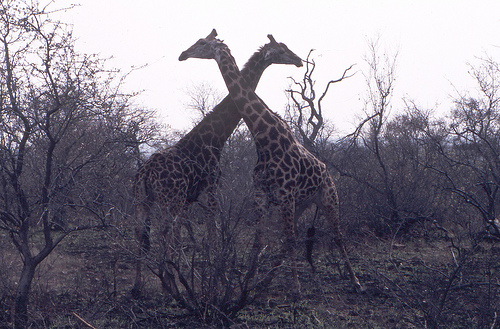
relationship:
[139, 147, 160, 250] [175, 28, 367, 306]
tail on animal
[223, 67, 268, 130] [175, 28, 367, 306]
neck on animal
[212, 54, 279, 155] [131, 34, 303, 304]
neck on animal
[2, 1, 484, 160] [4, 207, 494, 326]
sky above land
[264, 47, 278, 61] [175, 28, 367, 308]
ear on animal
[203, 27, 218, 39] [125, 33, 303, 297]
ear on animal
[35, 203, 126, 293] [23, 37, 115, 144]
branch on tree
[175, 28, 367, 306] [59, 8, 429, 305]
animal walking in it forest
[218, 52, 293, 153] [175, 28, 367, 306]
neck on animal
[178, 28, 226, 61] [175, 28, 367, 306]
giraffe head belonging to animal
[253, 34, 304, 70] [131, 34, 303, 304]
giraffe head belonging to animal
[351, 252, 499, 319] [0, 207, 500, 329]
twigs on land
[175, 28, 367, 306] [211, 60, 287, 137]
animal has neck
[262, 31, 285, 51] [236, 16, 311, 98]
ear on giraffe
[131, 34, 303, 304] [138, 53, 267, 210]
animal has spots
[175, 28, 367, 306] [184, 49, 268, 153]
animal twisting neck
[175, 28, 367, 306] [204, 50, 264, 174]
animal twisting neck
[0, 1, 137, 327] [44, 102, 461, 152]
tree with no leaves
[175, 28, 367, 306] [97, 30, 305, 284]
animal with giraffe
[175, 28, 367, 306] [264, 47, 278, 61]
animal with ear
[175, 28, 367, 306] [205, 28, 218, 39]
animal with ear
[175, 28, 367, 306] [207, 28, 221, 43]
animal in back with ears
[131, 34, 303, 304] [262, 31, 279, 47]
animal in back with ears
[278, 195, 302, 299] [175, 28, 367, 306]
leg of animal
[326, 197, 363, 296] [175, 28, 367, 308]
leg of animal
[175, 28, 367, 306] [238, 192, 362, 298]
animal with 4 legs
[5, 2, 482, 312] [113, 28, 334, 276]
savannah with giraffes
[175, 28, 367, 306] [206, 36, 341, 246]
animal with spots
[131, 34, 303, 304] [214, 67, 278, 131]
animal with neck